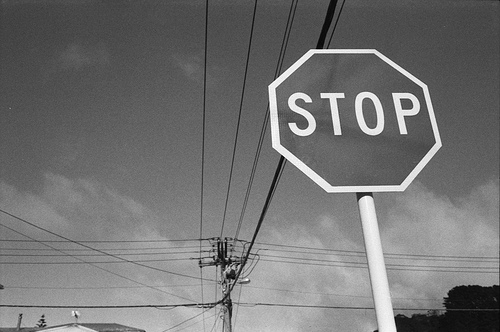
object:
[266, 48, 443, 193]
sign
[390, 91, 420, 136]
lettering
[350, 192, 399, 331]
pole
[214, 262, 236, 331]
pole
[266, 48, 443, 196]
border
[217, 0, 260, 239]
wires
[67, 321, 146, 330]
roof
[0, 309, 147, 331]
house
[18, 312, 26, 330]
chimney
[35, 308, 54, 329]
tree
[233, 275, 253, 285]
light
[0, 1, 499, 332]
photo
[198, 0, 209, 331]
lines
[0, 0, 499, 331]
sky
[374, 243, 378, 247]
part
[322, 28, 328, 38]
edge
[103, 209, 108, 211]
part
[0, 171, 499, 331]
cloud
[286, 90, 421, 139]
stop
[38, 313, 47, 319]
top